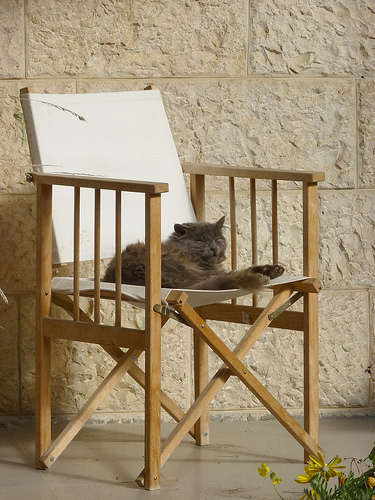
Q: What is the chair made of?
A: Wood.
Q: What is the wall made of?
A: Rocks.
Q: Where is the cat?
A: The chair.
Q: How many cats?
A: One.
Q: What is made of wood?
A: The chair.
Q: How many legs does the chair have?
A: Four.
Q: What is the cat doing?
A: Sleeping.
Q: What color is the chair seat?
A: White.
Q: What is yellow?
A: The flowers.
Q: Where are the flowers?
A: The ground.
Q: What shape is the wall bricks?
A: Rectangle.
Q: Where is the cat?
A: In the chair.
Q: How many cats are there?
A: 1.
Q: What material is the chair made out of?
A: Wood.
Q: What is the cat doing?
A: Sleeping.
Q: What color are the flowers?
A: Yellow.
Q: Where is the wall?
A: Behind the chair.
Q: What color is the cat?
A: Gray.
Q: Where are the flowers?
A: In front of the chair.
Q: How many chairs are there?
A: 1.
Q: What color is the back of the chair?
A: White.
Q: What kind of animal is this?
A: Cat.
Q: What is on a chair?
A: A cat.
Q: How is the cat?
A: Sleeping.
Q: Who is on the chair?
A: A cat.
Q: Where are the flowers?
A: Bottom right.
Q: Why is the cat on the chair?
A: Sleeping.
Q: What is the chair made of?
A: Wood.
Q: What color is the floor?
A: Gray.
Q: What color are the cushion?
A: White.